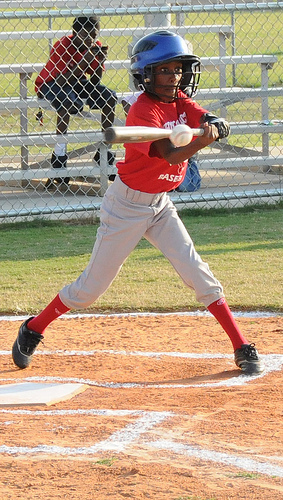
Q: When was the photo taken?
A: Daytime.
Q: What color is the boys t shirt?
A: Red.